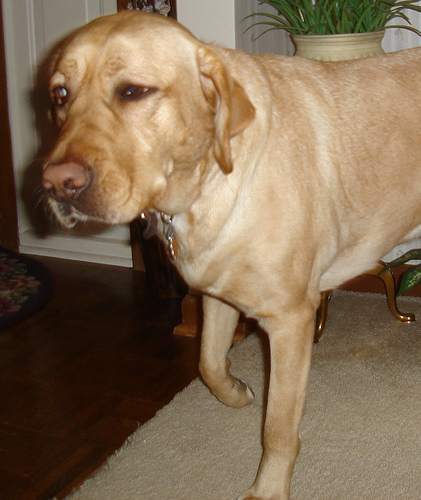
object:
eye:
[116, 75, 162, 102]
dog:
[34, 10, 420, 500]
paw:
[226, 376, 257, 412]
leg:
[250, 294, 318, 500]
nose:
[39, 161, 92, 197]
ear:
[199, 45, 256, 175]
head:
[39, 8, 238, 228]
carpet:
[60, 290, 420, 499]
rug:
[0, 251, 55, 330]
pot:
[290, 30, 387, 62]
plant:
[245, 0, 419, 38]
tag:
[165, 225, 178, 260]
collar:
[142, 171, 218, 222]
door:
[0, 84, 19, 253]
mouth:
[53, 203, 123, 229]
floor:
[6, 273, 170, 483]